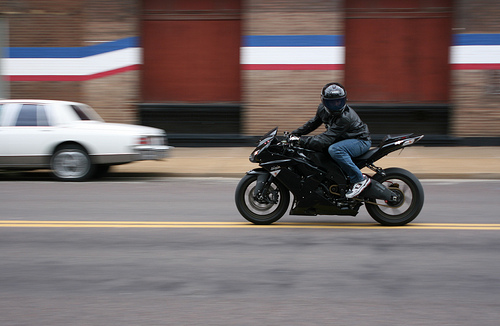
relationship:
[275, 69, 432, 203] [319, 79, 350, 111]
person wearing helmet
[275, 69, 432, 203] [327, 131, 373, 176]
person wearing jeans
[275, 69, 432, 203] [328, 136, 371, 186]
person wearing jeans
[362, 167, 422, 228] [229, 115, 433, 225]
wheel of motorcycle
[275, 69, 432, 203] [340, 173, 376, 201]
person wearing sneakers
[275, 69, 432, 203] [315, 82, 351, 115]
person wearing helmet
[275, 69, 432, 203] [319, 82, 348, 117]
person wearing helmet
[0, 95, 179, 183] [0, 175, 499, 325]
car parked on street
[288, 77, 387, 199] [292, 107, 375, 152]
man wearing black jacket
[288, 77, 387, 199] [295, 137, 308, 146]
man wearing gloves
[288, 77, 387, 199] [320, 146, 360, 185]
man wearing jeans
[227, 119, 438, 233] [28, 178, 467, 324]
motorcycle on street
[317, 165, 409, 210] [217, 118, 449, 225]
chain on motorcycle